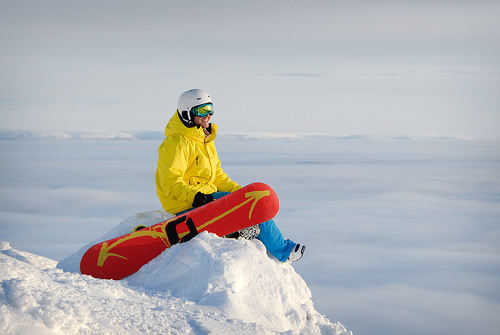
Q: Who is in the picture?
A: A woman.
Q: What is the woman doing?
A: Sitting.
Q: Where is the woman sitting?
A: The snow.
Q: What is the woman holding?
A: A snowboard.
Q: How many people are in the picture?
A: One.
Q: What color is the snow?
A: White.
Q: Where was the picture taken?
A: Mountain.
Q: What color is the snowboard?
A: Red and yellow.